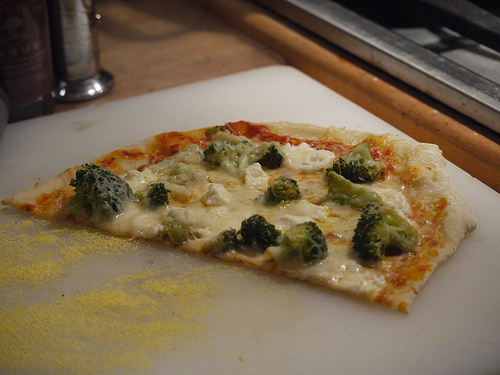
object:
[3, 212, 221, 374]
seasonings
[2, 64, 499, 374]
plate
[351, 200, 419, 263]
broccoli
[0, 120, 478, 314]
cheese topping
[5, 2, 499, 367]
table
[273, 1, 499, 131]
bar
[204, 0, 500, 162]
bar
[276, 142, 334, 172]
cheese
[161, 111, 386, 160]
tomato sauce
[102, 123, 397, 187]
sauce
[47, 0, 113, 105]
salt shaker